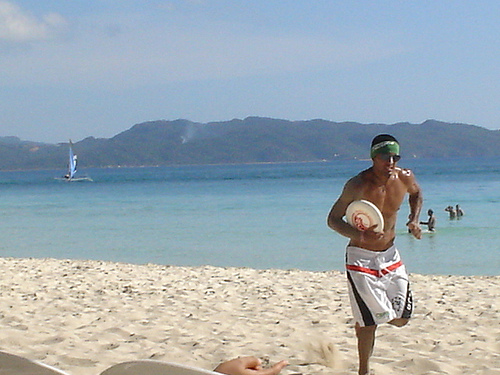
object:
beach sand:
[1, 269, 143, 334]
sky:
[0, 1, 497, 115]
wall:
[393, 160, 411, 185]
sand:
[1, 255, 101, 326]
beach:
[0, 258, 499, 373]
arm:
[325, 173, 361, 244]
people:
[421, 202, 466, 234]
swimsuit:
[343, 245, 414, 325]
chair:
[96, 358, 224, 373]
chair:
[1, 355, 70, 373]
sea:
[256, 161, 322, 197]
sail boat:
[51, 138, 98, 183]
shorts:
[341, 244, 414, 328]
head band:
[367, 132, 402, 159]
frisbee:
[343, 197, 386, 235]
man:
[324, 133, 426, 374]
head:
[370, 133, 402, 175]